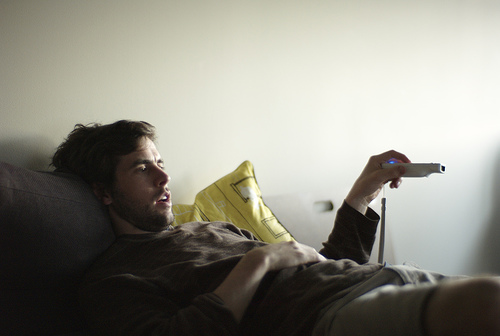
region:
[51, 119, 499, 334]
The man laying on the bed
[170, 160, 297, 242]
The yellow pillow behind the man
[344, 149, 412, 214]
The hand on the remote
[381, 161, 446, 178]
The remote is white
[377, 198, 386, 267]
The strap of the remote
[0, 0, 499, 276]
The white wall behind the man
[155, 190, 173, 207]
The mouth of the man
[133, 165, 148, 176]
The eye on the face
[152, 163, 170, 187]
The nose of the man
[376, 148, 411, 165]
The mans index finger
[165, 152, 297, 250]
yellow pillow behind man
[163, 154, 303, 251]
pillow behind man is yellow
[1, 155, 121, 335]
man laying on gray pillow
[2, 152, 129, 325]
man laying on pillow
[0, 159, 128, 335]
mans pillow is gray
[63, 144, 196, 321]
A man lying down.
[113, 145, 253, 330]
A man lying down.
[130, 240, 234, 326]
A man lying down.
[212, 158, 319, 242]
the pillow is yellow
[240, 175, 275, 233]
the pillow is yellow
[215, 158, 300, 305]
the pillow is yellow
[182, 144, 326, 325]
the pillow is yellow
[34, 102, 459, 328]
man holding a remote control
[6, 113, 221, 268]
his head on the pillow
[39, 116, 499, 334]
a man laying on the bed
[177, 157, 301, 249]
a yellow pillow on the bed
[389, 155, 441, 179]
a remote in the man's hand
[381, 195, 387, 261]
a cord hanging from the remote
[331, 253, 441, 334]
the underwear the man is wearing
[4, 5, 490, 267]
the wall that the bed is by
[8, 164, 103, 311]
a black pillow that the man's head is resting on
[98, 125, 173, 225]
the bored look on the man's face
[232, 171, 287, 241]
the pattern on the pillow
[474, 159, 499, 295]
a shadow on the wall